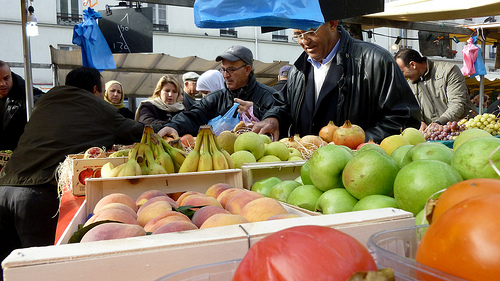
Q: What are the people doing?
A: Buying fruits.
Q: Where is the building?
A: On the left side.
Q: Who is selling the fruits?
A: A man.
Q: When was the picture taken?
A: Daytime.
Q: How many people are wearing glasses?
A: Two.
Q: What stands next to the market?
A: A building.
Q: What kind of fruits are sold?
A: Bananas,apples,oranges.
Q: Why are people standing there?
A: To buy fruits.